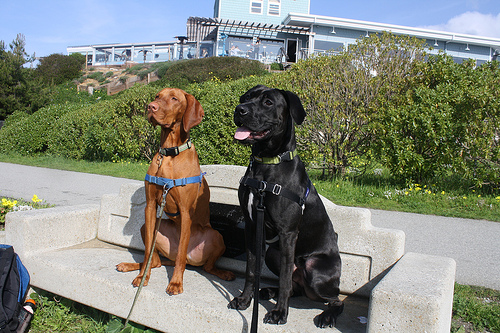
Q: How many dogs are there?
A: Two.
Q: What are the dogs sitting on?
A: A bench.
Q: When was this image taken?
A: Daytime.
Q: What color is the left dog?
A: Brown.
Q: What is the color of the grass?
A: Green.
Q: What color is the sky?
A: Blue.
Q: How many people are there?
A: None.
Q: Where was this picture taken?
A: In a park.